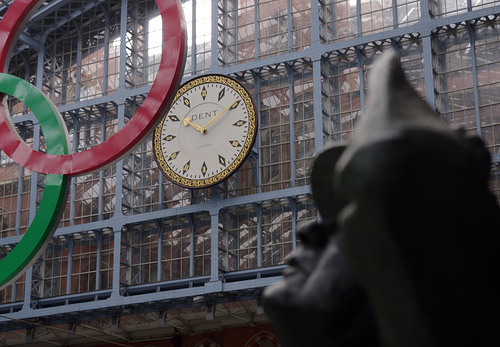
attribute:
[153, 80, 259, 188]
clock — gold, fancy, golden, dent, minute hand, hour hand, large, branding, wall, roman numeral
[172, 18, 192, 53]
ring — red, circular, big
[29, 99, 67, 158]
ring — green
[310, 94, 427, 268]
statue — brown, black, man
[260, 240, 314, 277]
lip — face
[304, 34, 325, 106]
metal — gray, large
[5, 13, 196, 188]
circle — red, big, large, olympic, half, connected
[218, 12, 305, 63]
window — lots, single, large set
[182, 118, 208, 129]
hand — gold